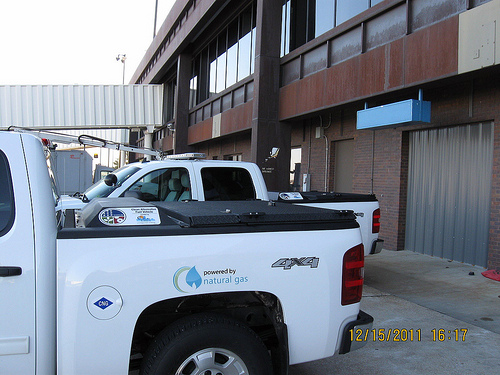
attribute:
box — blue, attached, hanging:
[356, 99, 432, 130]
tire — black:
[142, 312, 276, 373]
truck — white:
[2, 129, 363, 371]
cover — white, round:
[88, 284, 124, 319]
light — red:
[343, 245, 366, 308]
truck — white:
[64, 158, 384, 255]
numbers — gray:
[273, 255, 321, 270]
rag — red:
[481, 267, 500, 283]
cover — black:
[151, 197, 362, 235]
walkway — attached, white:
[2, 81, 169, 131]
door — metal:
[407, 121, 493, 267]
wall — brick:
[301, 118, 407, 250]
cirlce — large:
[172, 265, 250, 292]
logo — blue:
[187, 265, 251, 288]